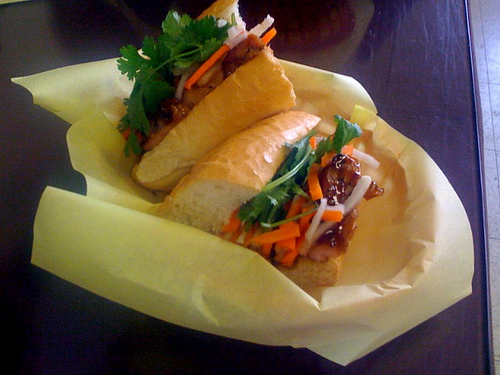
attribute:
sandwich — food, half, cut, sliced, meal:
[157, 109, 378, 294]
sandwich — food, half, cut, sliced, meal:
[117, 0, 297, 195]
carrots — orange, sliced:
[188, 26, 282, 89]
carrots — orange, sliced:
[226, 138, 355, 265]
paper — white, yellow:
[10, 50, 474, 366]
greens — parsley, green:
[241, 115, 363, 229]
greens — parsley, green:
[115, 8, 231, 151]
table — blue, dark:
[0, 2, 496, 372]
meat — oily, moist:
[308, 156, 369, 245]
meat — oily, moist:
[139, 35, 263, 147]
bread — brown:
[159, 110, 320, 240]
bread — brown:
[285, 226, 354, 300]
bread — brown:
[132, 48, 296, 200]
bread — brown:
[196, 0, 243, 24]